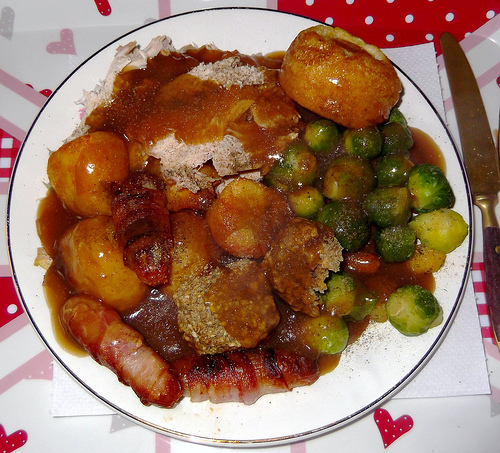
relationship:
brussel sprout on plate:
[290, 185, 324, 215] [6, 7, 473, 447]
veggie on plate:
[303, 130, 458, 262] [6, 7, 473, 447]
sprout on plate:
[384, 288, 449, 334] [6, 7, 473, 447]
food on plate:
[95, 179, 345, 339] [34, 22, 440, 379]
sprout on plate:
[384, 285, 440, 335] [6, 7, 473, 447]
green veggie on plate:
[321, 271, 356, 318] [6, 7, 473, 447]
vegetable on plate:
[361, 183, 414, 227] [6, 7, 473, 447]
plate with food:
[6, 7, 473, 447] [39, 23, 469, 408]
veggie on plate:
[302, 315, 349, 355] [6, 7, 473, 447]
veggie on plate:
[381, 229, 419, 257] [351, 336, 408, 389]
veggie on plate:
[402, 161, 454, 207] [351, 336, 408, 389]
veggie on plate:
[330, 201, 370, 252] [351, 336, 408, 389]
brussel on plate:
[384, 230, 416, 253] [195, 3, 267, 50]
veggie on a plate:
[298, 115, 343, 154] [6, 7, 473, 447]